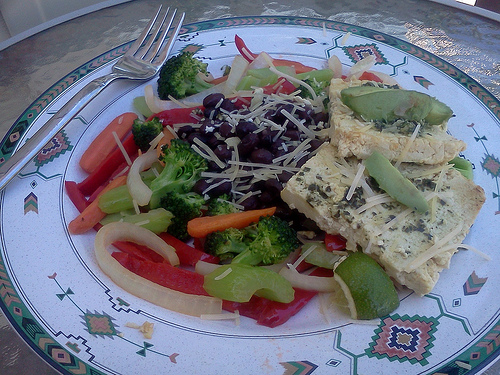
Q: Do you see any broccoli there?
A: Yes, there is broccoli.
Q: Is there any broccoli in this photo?
A: Yes, there is broccoli.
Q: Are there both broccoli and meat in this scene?
A: No, there is broccoli but no meat.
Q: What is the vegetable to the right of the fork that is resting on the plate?
A: The vegetable is broccoli.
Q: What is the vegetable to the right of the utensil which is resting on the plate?
A: The vegetable is broccoli.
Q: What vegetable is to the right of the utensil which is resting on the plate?
A: The vegetable is broccoli.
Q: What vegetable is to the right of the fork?
A: The vegetable is broccoli.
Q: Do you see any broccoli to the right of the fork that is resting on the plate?
A: Yes, there is broccoli to the right of the fork.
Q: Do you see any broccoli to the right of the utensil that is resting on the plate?
A: Yes, there is broccoli to the right of the fork.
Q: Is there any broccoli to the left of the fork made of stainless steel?
A: No, the broccoli is to the right of the fork.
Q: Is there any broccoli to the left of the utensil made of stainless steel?
A: No, the broccoli is to the right of the fork.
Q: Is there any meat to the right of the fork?
A: No, there is broccoli to the right of the fork.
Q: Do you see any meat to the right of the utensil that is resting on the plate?
A: No, there is broccoli to the right of the fork.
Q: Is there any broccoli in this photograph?
A: Yes, there is broccoli.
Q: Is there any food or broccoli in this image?
A: Yes, there is broccoli.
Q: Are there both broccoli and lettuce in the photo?
A: No, there is broccoli but no lettuce.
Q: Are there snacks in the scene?
A: No, there are no snacks.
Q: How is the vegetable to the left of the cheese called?
A: The vegetable is broccoli.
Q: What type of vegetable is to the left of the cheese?
A: The vegetable is broccoli.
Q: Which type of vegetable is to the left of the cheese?
A: The vegetable is broccoli.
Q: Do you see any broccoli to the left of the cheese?
A: Yes, there is broccoli to the left of the cheese.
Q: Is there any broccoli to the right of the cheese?
A: No, the broccoli is to the left of the cheese.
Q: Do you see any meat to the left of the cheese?
A: No, there is broccoli to the left of the cheese.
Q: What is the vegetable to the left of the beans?
A: The vegetable is broccoli.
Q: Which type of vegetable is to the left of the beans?
A: The vegetable is broccoli.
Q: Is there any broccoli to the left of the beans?
A: Yes, there is broccoli to the left of the beans.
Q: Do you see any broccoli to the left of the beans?
A: Yes, there is broccoli to the left of the beans.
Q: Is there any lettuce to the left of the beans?
A: No, there is broccoli to the left of the beans.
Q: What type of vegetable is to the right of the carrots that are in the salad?
A: The vegetable is broccoli.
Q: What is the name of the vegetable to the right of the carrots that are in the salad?
A: The vegetable is broccoli.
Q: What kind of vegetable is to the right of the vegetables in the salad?
A: The vegetable is broccoli.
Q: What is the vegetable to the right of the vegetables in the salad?
A: The vegetable is broccoli.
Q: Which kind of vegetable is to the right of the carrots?
A: The vegetable is broccoli.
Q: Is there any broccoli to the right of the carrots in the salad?
A: Yes, there is broccoli to the right of the carrots.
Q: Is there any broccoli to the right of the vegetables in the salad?
A: Yes, there is broccoli to the right of the carrots.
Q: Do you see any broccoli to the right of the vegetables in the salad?
A: Yes, there is broccoli to the right of the carrots.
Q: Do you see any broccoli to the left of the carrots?
A: No, the broccoli is to the right of the carrots.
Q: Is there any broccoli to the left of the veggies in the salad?
A: No, the broccoli is to the right of the carrots.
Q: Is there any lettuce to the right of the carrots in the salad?
A: No, there is broccoli to the right of the carrots.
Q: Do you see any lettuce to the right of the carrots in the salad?
A: No, there is broccoli to the right of the carrots.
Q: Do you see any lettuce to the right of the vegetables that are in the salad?
A: No, there is broccoli to the right of the carrots.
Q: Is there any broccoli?
A: Yes, there is broccoli.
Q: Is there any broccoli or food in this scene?
A: Yes, there is broccoli.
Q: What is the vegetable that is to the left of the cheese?
A: The vegetable is broccoli.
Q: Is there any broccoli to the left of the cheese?
A: Yes, there is broccoli to the left of the cheese.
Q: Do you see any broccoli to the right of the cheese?
A: No, the broccoli is to the left of the cheese.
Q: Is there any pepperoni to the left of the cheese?
A: No, there is broccoli to the left of the cheese.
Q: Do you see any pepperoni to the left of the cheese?
A: No, there is broccoli to the left of the cheese.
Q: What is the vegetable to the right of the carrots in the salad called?
A: The vegetable is broccoli.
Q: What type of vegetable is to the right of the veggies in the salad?
A: The vegetable is broccoli.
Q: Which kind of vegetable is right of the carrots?
A: The vegetable is broccoli.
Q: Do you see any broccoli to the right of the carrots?
A: Yes, there is broccoli to the right of the carrots.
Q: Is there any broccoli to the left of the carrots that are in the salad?
A: No, the broccoli is to the right of the carrots.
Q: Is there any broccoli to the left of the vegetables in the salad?
A: No, the broccoli is to the right of the carrots.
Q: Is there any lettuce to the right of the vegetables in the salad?
A: No, there is broccoli to the right of the carrots.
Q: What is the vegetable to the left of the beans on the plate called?
A: The vegetable is broccoli.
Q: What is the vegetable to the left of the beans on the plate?
A: The vegetable is broccoli.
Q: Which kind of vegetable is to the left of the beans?
A: The vegetable is broccoli.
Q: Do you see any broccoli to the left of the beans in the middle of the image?
A: Yes, there is broccoli to the left of the beans.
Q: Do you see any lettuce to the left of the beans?
A: No, there is broccoli to the left of the beans.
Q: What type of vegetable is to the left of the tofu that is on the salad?
A: The vegetable is broccoli.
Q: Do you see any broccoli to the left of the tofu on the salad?
A: Yes, there is broccoli to the left of the tofu.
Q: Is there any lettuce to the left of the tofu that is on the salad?
A: No, there is broccoli to the left of the tofu.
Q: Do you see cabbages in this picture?
A: No, there are no cabbages.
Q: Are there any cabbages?
A: No, there are no cabbages.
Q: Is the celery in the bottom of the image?
A: Yes, the celery is in the bottom of the image.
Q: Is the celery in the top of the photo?
A: No, the celery is in the bottom of the image.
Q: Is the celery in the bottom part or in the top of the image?
A: The celery is in the bottom of the image.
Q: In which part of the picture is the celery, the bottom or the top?
A: The celery is in the bottom of the image.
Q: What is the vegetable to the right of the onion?
A: The vegetable is a celery.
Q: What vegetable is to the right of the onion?
A: The vegetable is a celery.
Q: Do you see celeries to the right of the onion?
A: Yes, there is a celery to the right of the onion.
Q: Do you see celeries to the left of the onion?
A: No, the celery is to the right of the onion.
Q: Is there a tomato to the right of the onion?
A: No, there is a celery to the right of the onion.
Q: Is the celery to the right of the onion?
A: Yes, the celery is to the right of the onion.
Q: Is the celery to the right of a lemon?
A: No, the celery is to the right of the onion.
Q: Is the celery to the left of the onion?
A: No, the celery is to the right of the onion.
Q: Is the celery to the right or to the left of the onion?
A: The celery is to the right of the onion.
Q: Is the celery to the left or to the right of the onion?
A: The celery is to the right of the onion.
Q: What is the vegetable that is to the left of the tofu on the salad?
A: The vegetable is a celery.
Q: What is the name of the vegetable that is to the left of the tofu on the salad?
A: The vegetable is a celery.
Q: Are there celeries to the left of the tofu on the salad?
A: Yes, there is a celery to the left of the tofu.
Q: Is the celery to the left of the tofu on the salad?
A: Yes, the celery is to the left of the tofu.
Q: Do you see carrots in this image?
A: Yes, there are carrots.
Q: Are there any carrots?
A: Yes, there are carrots.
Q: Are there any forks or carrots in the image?
A: Yes, there are carrots.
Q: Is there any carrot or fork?
A: Yes, there are carrots.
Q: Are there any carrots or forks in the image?
A: Yes, there are carrots.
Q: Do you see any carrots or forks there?
A: Yes, there are carrots.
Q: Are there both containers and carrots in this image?
A: No, there are carrots but no containers.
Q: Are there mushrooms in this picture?
A: No, there are no mushrooms.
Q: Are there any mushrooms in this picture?
A: No, there are no mushrooms.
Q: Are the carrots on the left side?
A: Yes, the carrots are on the left of the image.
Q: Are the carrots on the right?
A: No, the carrots are on the left of the image.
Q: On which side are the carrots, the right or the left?
A: The carrots are on the left of the image.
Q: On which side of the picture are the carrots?
A: The carrots are on the left of the image.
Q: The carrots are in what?
A: The carrots are in the salad.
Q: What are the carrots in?
A: The carrots are in the salad.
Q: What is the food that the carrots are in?
A: The food is salad.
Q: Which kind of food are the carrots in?
A: The carrots are in the salad.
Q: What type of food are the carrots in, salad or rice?
A: The carrots are in salad.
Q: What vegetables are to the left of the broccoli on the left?
A: The vegetables are carrots.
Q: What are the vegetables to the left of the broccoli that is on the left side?
A: The vegetables are carrots.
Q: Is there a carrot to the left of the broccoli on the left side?
A: Yes, there are carrots to the left of the broccoli.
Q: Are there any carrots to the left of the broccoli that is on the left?
A: Yes, there are carrots to the left of the broccoli.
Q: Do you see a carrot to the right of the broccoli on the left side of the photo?
A: No, the carrots are to the left of the broccoli.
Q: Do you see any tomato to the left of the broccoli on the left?
A: No, there are carrots to the left of the broccoli.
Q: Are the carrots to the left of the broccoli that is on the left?
A: Yes, the carrots are to the left of the broccoli.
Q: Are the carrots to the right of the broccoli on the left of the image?
A: No, the carrots are to the left of the broccoli.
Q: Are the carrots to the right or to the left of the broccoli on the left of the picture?
A: The carrots are to the left of the broccoli.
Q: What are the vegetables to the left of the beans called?
A: The vegetables are carrots.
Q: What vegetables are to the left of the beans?
A: The vegetables are carrots.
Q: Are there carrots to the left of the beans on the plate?
A: Yes, there are carrots to the left of the beans.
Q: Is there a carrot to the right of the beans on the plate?
A: No, the carrots are to the left of the beans.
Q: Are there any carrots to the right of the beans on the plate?
A: No, the carrots are to the left of the beans.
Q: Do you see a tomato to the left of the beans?
A: No, there are carrots to the left of the beans.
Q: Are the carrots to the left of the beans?
A: Yes, the carrots are to the left of the beans.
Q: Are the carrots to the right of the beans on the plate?
A: No, the carrots are to the left of the beans.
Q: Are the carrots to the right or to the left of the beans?
A: The carrots are to the left of the beans.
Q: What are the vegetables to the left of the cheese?
A: The vegetables are carrots.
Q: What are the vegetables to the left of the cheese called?
A: The vegetables are carrots.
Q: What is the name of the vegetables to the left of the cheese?
A: The vegetables are carrots.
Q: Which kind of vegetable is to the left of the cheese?
A: The vegetables are carrots.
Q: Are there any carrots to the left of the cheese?
A: Yes, there are carrots to the left of the cheese.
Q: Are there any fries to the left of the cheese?
A: No, there are carrots to the left of the cheese.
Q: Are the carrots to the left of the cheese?
A: Yes, the carrots are to the left of the cheese.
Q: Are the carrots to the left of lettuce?
A: No, the carrots are to the left of the cheese.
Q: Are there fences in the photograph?
A: No, there are no fences.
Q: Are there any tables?
A: Yes, there is a table.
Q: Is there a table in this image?
A: Yes, there is a table.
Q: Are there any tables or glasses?
A: Yes, there is a table.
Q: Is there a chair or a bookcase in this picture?
A: No, there are no chairs or bookcases.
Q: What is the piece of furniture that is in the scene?
A: The piece of furniture is a table.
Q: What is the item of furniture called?
A: The piece of furniture is a table.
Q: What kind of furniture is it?
A: The piece of furniture is a table.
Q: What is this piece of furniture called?
A: This is a table.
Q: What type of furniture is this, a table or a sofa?
A: This is a table.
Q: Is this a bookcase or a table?
A: This is a table.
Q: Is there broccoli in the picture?
A: Yes, there is broccoli.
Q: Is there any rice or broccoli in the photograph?
A: Yes, there is broccoli.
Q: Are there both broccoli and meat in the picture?
A: No, there is broccoli but no meat.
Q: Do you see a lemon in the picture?
A: No, there are no lemons.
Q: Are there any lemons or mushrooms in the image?
A: No, there are no lemons or mushrooms.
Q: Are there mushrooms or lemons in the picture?
A: No, there are no lemons or mushrooms.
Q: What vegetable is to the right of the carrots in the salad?
A: The vegetable is broccoli.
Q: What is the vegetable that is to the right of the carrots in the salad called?
A: The vegetable is broccoli.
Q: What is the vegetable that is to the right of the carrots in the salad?
A: The vegetable is broccoli.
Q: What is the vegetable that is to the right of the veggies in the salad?
A: The vegetable is broccoli.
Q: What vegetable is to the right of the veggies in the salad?
A: The vegetable is broccoli.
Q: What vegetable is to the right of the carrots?
A: The vegetable is broccoli.